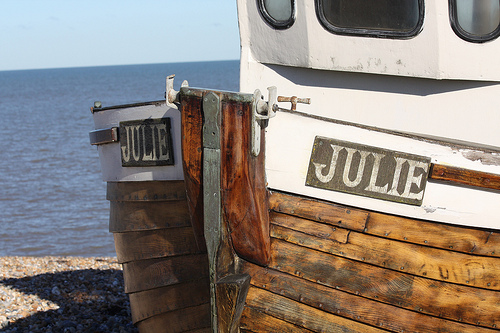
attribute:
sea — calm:
[23, 32, 109, 144]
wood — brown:
[84, 77, 494, 332]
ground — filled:
[51, 257, 83, 310]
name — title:
[300, 133, 433, 209]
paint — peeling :
[437, 142, 498, 173]